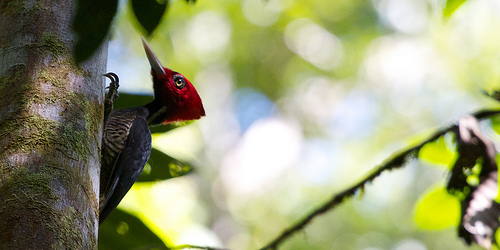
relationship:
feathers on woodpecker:
[121, 106, 186, 125] [97, 32, 204, 222]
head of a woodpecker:
[151, 68, 204, 120] [95, 36, 208, 228]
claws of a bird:
[92, 73, 125, 190] [108, 40, 206, 220]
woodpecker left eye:
[97, 32, 204, 222] [172, 73, 185, 89]